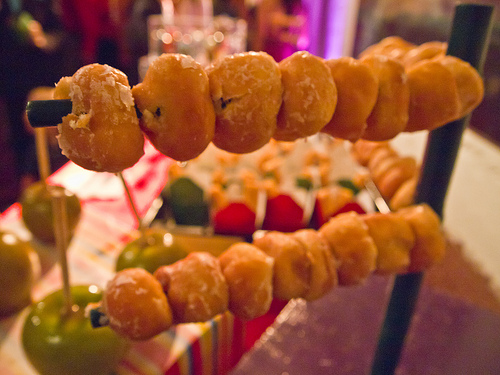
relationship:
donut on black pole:
[53, 63, 145, 175] [25, 99, 72, 129]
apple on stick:
[20, 281, 130, 373] [49, 187, 72, 294]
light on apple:
[87, 282, 102, 295] [25, 278, 116, 370]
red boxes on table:
[210, 182, 375, 234] [1, 121, 366, 373]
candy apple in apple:
[50, 190, 71, 316] [20, 281, 130, 373]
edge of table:
[237, 296, 295, 373] [0, 82, 389, 373]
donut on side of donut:
[53, 63, 145, 175] [35, 40, 141, 190]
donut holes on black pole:
[131, 36, 486, 162] [27, 97, 70, 130]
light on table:
[82, 182, 120, 227] [44, 82, 429, 354]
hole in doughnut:
[219, 92, 238, 113] [209, 46, 283, 155]